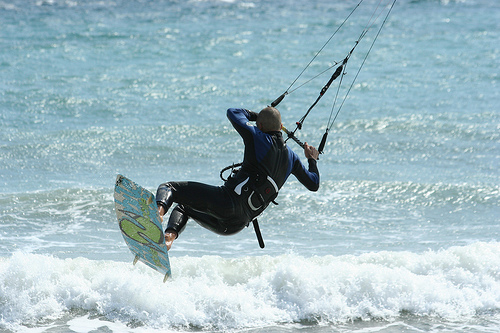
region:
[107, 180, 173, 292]
A blue board in the air.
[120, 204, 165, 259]
A logo on the board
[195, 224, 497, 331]
Wave on the water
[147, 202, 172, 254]
The bare feet on the board.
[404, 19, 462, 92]
Ripples on the water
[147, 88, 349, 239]
A man hands onto handle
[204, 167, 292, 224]
Harness on the man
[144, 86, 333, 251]
The man wears a wetsuit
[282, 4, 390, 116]
The string on the kite.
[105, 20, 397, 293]
The man is kite surfing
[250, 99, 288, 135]
the head of a man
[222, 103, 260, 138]
the arm of a man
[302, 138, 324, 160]
the hand of a man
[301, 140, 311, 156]
the thumb of a man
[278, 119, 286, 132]
the ear of a man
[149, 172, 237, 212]
the leg of a man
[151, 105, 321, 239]
a black and blue wet suit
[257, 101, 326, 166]
a handle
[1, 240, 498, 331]
a white foaming wave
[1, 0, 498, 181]
calm water behind the wave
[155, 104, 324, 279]
parasailer in mid air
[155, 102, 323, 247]
parasailer in a wet suit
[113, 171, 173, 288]
the board under the parasailer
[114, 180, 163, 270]
designs under the board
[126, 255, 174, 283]
the fins under the board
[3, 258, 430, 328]
the white waves breaking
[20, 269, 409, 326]
the small white waves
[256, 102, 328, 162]
the handle for the parasail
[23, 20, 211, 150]
the ocean water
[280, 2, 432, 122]
the chords on the parasail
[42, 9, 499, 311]
a man parasailing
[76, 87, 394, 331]
a man in a wet suit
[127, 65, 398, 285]
a mam holding onto the parasail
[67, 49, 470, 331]
a man in the air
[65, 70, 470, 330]
a parasailer in the air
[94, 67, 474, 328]
a parasailer holding on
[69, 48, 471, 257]
a parasailer in a wetsuit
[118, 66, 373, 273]
a parasailer wearing a wetsuit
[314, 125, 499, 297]
a body of water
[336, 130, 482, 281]
a body of wavy water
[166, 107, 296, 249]
black and blue rashguard